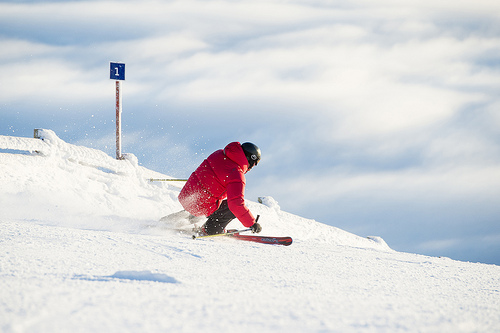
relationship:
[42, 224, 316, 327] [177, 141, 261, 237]
snow behind person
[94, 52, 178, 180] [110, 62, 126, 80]
post in square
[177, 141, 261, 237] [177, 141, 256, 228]
person wearing coat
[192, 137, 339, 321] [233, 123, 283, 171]
man wearing helmet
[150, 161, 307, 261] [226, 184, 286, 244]
poles in hand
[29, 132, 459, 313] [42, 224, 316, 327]
ground covered snow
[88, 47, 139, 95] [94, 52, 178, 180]
square on post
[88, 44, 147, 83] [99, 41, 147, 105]
1 in square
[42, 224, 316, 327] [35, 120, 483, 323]
snow in ground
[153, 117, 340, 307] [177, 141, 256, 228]
person wearing coat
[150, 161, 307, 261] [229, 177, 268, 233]
poles in hand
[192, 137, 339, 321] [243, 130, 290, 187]
man wearing helmet